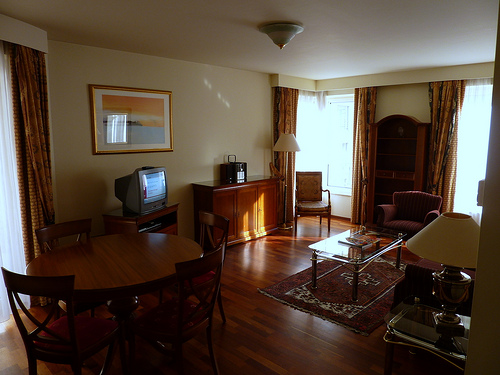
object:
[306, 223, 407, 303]
coffee table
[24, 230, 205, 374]
table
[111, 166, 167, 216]
television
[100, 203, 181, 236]
stand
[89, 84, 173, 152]
picture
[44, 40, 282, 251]
wall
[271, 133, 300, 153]
lamp shade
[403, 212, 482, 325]
lamp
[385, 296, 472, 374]
end table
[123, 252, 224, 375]
chair by table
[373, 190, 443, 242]
arm chair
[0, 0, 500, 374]
room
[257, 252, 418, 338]
carpet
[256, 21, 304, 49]
light fixture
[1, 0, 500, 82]
ceiling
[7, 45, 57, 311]
curtain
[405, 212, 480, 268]
lamp shade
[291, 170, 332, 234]
chair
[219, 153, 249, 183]
radio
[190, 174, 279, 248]
stand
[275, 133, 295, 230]
lamp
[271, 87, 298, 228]
curtain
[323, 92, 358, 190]
window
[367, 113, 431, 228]
book shelf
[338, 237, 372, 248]
magazines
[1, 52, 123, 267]
chair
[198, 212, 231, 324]
chair